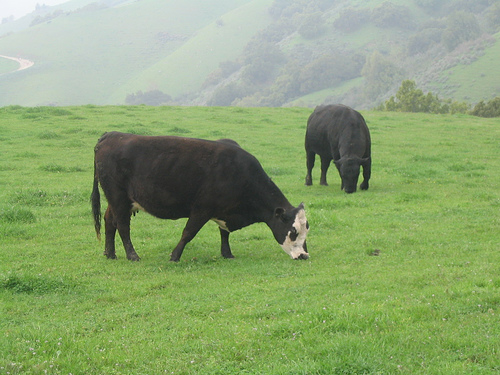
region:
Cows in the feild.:
[78, 94, 389, 261]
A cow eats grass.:
[261, 192, 328, 274]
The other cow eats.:
[292, 94, 381, 199]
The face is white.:
[263, 203, 319, 270]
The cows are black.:
[56, 39, 384, 269]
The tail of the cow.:
[89, 163, 108, 245]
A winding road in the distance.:
[4, 34, 34, 87]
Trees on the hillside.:
[117, 2, 467, 104]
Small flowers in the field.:
[393, 263, 463, 355]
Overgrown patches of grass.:
[1, 98, 71, 328]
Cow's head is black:
[329, 148, 374, 195]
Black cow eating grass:
[291, 92, 395, 199]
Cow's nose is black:
[340, 184, 362, 195]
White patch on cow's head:
[296, 211, 306, 224]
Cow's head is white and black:
[260, 191, 325, 278]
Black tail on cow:
[83, 142, 110, 257]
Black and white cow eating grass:
[68, 120, 318, 279]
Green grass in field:
[268, 293, 401, 353]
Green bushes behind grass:
[385, 77, 448, 117]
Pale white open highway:
[0, 44, 41, 81]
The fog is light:
[28, 15, 494, 110]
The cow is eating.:
[56, 125, 343, 299]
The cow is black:
[54, 113, 336, 297]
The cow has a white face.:
[258, 201, 328, 256]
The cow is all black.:
[293, 76, 396, 223]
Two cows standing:
[58, 93, 396, 277]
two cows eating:
[58, 93, 413, 280]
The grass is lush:
[74, 277, 496, 372]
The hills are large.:
[12, 1, 486, 374]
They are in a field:
[15, 20, 447, 370]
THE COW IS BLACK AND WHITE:
[285, 241, 296, 250]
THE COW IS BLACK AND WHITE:
[294, 236, 300, 262]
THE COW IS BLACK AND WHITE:
[284, 243, 301, 265]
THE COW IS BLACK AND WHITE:
[287, 242, 298, 257]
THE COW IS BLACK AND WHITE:
[287, 240, 296, 245]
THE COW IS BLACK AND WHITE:
[286, 243, 293, 244]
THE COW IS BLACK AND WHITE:
[284, 235, 295, 249]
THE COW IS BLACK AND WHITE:
[288, 245, 300, 249]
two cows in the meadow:
[73, 94, 385, 284]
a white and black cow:
[76, 119, 322, 279]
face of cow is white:
[273, 205, 322, 267]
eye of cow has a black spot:
[288, 224, 304, 244]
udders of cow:
[125, 197, 147, 222]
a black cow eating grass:
[290, 97, 385, 198]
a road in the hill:
[2, 45, 42, 87]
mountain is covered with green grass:
[37, 5, 497, 100]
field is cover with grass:
[11, 99, 497, 370]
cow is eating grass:
[76, 123, 320, 285]